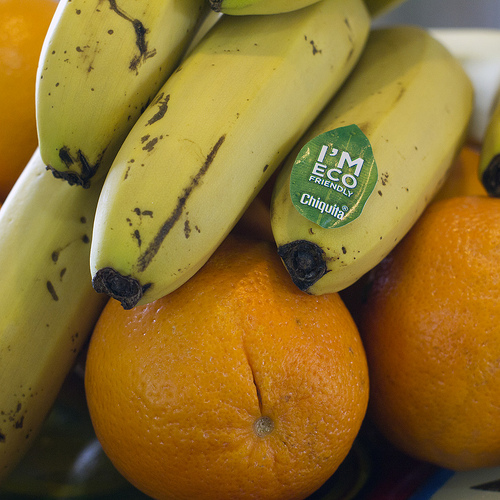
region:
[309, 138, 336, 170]
the white letter I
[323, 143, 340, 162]
this is an aprostrophe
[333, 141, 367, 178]
the white letter M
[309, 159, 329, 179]
the white letter E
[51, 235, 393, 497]
this is an orange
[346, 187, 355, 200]
the white letter I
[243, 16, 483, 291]
this is a banana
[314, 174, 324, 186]
the white letter R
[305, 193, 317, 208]
the white letter H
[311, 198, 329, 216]
the white letter Q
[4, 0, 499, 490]
yellow and orange fruit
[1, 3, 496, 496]
the fruits haven't been eaten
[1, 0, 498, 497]
the fruits haven't been peeled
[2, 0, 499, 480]
unpeeled fruits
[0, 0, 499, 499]
oranges and bananas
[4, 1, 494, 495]
a bunch of bananas on top of oranges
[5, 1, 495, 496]
a pile of oranges and bananas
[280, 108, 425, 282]
a green sticker on a banana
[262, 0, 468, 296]
the banana and sticker are eco friendly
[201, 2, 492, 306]
a Chiquita brand banana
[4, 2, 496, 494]
bananas on top of oranges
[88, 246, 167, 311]
black tip of banana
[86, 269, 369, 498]
dimpled skin of orange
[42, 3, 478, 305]
skin of three bananas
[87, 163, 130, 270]
light reflection on banana skin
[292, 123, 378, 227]
sticker with white words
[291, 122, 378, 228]
peeling sticker of banana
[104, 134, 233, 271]
black marks on banana skin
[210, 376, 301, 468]
creases around orange navel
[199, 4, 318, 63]
shadow on banana skin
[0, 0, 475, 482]
bunch of yellow bananas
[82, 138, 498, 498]
oranges underneath bunch of bananas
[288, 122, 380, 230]
green and white sticker on banana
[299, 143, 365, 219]
white lettering on green sticker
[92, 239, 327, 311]
blackened ends of yellow bananas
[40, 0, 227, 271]
black bruising on yellow bananas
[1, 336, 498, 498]
multi-colored table covering under fruit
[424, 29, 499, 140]
white background behind fruit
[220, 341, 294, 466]
pit end of orange with indentions in it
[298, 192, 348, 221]
brand of banana in white lettering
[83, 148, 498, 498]
the oranges in the pile of fruits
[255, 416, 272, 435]
the navel on the orange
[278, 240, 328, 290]
the black end of the banana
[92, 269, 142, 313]
the black end of the banana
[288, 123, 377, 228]
the sticker on the banana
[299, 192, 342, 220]
the word Chiquita on the sticker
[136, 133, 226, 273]
the long brown spot on the banana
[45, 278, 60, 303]
the brown spot on the banana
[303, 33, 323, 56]
the brown spot on the banana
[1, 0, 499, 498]
the pile of bananas and oranges